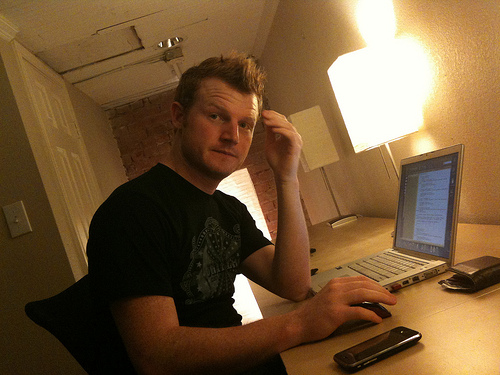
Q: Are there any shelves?
A: No, there are no shelves.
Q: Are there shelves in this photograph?
A: No, there are no shelves.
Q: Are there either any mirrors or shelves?
A: No, there are no shelves or mirrors.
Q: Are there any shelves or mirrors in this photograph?
A: No, there are no shelves or mirrors.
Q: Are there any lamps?
A: Yes, there is a lamp.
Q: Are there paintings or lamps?
A: Yes, there is a lamp.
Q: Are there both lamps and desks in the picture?
A: Yes, there are both a lamp and a desk.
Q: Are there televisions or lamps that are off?
A: Yes, the lamp is off.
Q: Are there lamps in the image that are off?
A: Yes, there is a lamp that is off.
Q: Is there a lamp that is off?
A: Yes, there is a lamp that is off.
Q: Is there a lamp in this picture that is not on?
A: Yes, there is a lamp that is off.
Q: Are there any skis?
A: No, there are no skis.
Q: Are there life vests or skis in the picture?
A: No, there are no skis or life vests.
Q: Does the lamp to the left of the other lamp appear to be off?
A: Yes, the lamp is off.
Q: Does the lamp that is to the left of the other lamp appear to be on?
A: No, the lamp is off.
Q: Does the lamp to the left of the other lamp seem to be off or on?
A: The lamp is off.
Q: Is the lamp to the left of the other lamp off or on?
A: The lamp is off.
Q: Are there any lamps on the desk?
A: Yes, there is a lamp on the desk.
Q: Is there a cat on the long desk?
A: No, there is a lamp on the desk.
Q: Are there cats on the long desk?
A: No, there is a lamp on the desk.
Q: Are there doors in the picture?
A: Yes, there is a door.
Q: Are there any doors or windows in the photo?
A: Yes, there is a door.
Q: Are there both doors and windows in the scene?
A: No, there is a door but no windows.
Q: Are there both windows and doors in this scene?
A: No, there is a door but no windows.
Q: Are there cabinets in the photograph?
A: No, there are no cabinets.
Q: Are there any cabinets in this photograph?
A: No, there are no cabinets.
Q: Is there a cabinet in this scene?
A: No, there are no cabinets.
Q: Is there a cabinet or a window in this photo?
A: No, there are no cabinets or windows.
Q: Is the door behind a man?
A: Yes, the door is behind a man.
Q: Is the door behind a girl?
A: No, the door is behind a man.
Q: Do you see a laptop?
A: Yes, there is a laptop.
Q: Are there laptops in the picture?
A: Yes, there is a laptop.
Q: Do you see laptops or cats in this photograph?
A: Yes, there is a laptop.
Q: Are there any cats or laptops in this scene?
A: Yes, there is a laptop.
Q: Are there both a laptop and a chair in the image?
A: Yes, there are both a laptop and a chair.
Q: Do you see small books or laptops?
A: Yes, there is a small laptop.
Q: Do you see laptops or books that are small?
A: Yes, the laptop is small.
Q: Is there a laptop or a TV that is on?
A: Yes, the laptop is on.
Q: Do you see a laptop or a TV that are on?
A: Yes, the laptop is on.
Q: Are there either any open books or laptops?
A: Yes, there is an open laptop.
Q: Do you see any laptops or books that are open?
A: Yes, the laptop is open.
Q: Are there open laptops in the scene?
A: Yes, there is an open laptop.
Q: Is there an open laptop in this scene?
A: Yes, there is an open laptop.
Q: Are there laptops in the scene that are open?
A: Yes, there is a laptop that is open.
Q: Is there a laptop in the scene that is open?
A: Yes, there is a laptop that is open.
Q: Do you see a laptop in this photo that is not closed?
A: Yes, there is a open laptop.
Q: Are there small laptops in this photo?
A: Yes, there is a small laptop.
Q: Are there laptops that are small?
A: Yes, there is a laptop that is small.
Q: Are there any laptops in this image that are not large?
A: Yes, there is a small laptop.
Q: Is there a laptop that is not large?
A: Yes, there is a small laptop.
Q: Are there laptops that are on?
A: Yes, there is a laptop that is on.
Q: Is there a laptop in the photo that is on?
A: Yes, there is a laptop that is on.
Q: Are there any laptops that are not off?
A: Yes, there is a laptop that is on.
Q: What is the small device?
A: The device is a laptop.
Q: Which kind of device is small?
A: The device is a laptop.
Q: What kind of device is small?
A: The device is a laptop.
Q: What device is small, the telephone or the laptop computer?
A: The laptop computer is small.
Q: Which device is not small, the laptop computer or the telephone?
A: The telephone is not small.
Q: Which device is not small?
A: The device is a phone.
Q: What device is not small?
A: The device is a phone.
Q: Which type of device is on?
A: The device is a laptop.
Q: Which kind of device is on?
A: The device is a laptop.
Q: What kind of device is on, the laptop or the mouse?
A: The laptop is on.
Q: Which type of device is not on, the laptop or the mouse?
A: The mouse is not on.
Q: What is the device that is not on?
A: The device is a computer mouse.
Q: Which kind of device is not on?
A: The device is a computer mouse.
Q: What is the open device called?
A: The device is a laptop.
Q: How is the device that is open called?
A: The device is a laptop.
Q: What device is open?
A: The device is a laptop.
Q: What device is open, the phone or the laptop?
A: The laptop is open.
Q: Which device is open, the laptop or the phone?
A: The laptop is open.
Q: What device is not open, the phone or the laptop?
A: The phone is not open.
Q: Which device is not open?
A: The device is a phone.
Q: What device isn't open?
A: The device is a phone.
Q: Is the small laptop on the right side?
A: Yes, the laptop is on the right of the image.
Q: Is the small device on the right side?
A: Yes, the laptop is on the right of the image.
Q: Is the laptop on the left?
A: No, the laptop is on the right of the image.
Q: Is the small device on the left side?
A: No, the laptop is on the right of the image.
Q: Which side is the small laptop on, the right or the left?
A: The laptop is on the right of the image.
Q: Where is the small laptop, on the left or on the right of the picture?
A: The laptop is on the right of the image.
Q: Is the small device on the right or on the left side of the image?
A: The laptop is on the right of the image.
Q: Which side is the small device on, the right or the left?
A: The laptop is on the right of the image.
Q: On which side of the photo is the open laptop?
A: The laptop is on the right of the image.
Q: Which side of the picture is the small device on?
A: The laptop is on the right of the image.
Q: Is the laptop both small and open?
A: Yes, the laptop is small and open.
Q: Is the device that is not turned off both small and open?
A: Yes, the laptop is small and open.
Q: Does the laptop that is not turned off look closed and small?
A: No, the laptop computer is small but open.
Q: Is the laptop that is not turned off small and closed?
A: No, the laptop computer is small but open.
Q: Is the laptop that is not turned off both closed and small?
A: No, the laptop computer is small but open.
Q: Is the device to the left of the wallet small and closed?
A: No, the laptop computer is small but open.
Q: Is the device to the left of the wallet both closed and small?
A: No, the laptop computer is small but open.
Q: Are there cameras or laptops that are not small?
A: No, there is a laptop but it is small.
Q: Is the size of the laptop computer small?
A: Yes, the laptop computer is small.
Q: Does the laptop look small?
A: Yes, the laptop is small.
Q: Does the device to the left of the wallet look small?
A: Yes, the laptop is small.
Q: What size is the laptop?
A: The laptop is small.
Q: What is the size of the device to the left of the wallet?
A: The laptop is small.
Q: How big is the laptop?
A: The laptop is small.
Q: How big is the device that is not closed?
A: The laptop is small.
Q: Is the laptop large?
A: No, the laptop is small.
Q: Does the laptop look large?
A: No, the laptop is small.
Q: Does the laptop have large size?
A: No, the laptop is small.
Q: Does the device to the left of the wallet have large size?
A: No, the laptop is small.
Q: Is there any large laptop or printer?
A: No, there is a laptop but it is small.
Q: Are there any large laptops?
A: No, there is a laptop but it is small.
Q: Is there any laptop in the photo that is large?
A: No, there is a laptop but it is small.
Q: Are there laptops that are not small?
A: No, there is a laptop but it is small.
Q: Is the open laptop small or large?
A: The laptop is small.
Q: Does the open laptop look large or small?
A: The laptop is small.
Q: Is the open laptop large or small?
A: The laptop is small.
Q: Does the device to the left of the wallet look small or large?
A: The laptop is small.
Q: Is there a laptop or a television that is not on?
A: No, there is a laptop but it is on.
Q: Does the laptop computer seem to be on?
A: Yes, the laptop computer is on.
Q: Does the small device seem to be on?
A: Yes, the laptop computer is on.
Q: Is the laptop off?
A: No, the laptop is on.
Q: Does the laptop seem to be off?
A: No, the laptop is on.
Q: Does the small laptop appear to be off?
A: No, the laptop is on.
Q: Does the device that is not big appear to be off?
A: No, the laptop is on.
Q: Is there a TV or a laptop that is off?
A: No, there is a laptop but it is on.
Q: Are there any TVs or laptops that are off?
A: No, there is a laptop but it is on.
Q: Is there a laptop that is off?
A: No, there is a laptop but it is on.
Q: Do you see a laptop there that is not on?
A: No, there is a laptop but it is on.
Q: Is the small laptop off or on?
A: The laptop is on.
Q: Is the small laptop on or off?
A: The laptop is on.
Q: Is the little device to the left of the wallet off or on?
A: The laptop is on.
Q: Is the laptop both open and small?
A: Yes, the laptop is open and small.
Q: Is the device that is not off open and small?
A: Yes, the laptop is open and small.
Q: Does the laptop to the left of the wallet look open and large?
A: No, the laptop is open but small.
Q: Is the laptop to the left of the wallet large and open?
A: No, the laptop is open but small.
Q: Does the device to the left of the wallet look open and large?
A: No, the laptop is open but small.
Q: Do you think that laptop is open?
A: Yes, the laptop is open.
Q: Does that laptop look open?
A: Yes, the laptop is open.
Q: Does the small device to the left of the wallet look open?
A: Yes, the laptop is open.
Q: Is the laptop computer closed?
A: No, the laptop computer is open.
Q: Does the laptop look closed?
A: No, the laptop is open.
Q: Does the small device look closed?
A: No, the laptop is open.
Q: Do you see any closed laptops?
A: No, there is a laptop but it is open.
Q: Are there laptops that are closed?
A: No, there is a laptop but it is open.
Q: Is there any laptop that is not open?
A: No, there is a laptop but it is open.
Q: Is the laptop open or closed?
A: The laptop is open.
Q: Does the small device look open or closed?
A: The laptop is open.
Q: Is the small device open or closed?
A: The laptop is open.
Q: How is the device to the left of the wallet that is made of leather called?
A: The device is a laptop.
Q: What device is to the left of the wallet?
A: The device is a laptop.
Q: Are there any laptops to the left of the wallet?
A: Yes, there is a laptop to the left of the wallet.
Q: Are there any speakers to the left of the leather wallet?
A: No, there is a laptop to the left of the wallet.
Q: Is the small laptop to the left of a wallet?
A: Yes, the laptop is to the left of a wallet.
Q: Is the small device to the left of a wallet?
A: Yes, the laptop is to the left of a wallet.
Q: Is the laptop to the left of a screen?
A: No, the laptop is to the left of a wallet.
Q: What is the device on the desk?
A: The device is a laptop.